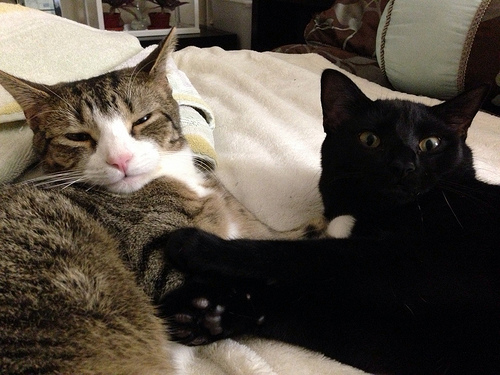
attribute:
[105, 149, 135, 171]
nose — pink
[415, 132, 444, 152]
eye — yellow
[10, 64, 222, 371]
cat — striped, fuzzy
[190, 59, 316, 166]
blanket — white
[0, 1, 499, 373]
duvet — white cover, white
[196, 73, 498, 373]
cat — black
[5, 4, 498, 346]
blanket — fleece, white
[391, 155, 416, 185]
nose — black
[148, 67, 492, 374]
cat — wide open, black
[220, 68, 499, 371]
cat — black